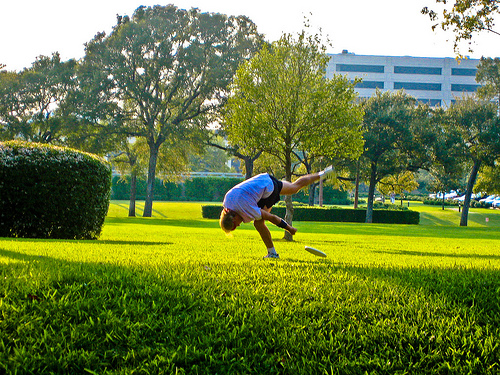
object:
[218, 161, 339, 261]
man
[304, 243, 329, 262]
frisbee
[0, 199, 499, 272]
grass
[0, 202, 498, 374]
field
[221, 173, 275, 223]
shirt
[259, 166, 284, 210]
shorts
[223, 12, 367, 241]
tree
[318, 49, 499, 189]
building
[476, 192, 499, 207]
car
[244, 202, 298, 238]
arm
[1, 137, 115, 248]
shrub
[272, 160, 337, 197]
leg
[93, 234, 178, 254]
shadow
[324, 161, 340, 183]
sneaker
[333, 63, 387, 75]
window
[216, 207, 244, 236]
head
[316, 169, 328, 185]
sock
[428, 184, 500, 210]
parking lot